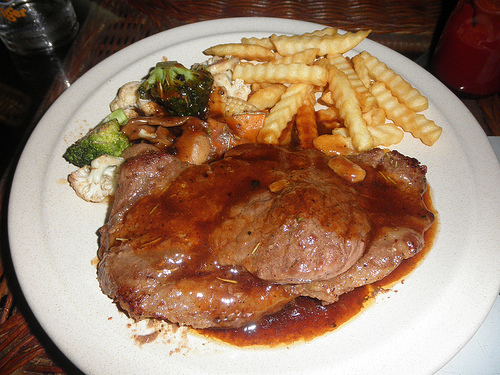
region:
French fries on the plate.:
[219, 44, 414, 136]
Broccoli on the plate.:
[71, 121, 138, 164]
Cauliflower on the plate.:
[53, 158, 115, 208]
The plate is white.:
[18, 220, 105, 335]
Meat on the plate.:
[136, 195, 391, 313]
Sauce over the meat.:
[163, 169, 358, 234]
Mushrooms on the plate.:
[118, 108, 200, 148]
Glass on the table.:
[3, 0, 79, 55]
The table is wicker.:
[91, 2, 266, 36]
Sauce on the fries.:
[276, 95, 338, 137]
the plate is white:
[43, 247, 120, 343]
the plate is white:
[68, 289, 158, 369]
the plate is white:
[16, 246, 142, 371]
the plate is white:
[33, 197, 176, 349]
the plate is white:
[52, 280, 92, 322]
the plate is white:
[61, 261, 213, 371]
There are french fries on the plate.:
[257, 19, 390, 136]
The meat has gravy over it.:
[297, 162, 429, 293]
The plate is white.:
[318, 240, 450, 373]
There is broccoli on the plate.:
[131, 58, 218, 110]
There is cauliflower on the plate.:
[52, 152, 129, 207]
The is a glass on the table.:
[2, 28, 79, 80]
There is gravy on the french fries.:
[311, 137, 403, 201]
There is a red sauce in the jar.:
[430, 30, 497, 92]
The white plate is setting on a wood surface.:
[4, 287, 75, 367]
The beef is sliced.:
[240, 217, 417, 339]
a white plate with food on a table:
[12, 1, 480, 366]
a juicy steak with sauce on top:
[110, 162, 418, 315]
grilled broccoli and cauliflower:
[65, 61, 150, 188]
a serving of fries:
[226, 26, 444, 151]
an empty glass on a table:
[0, 0, 85, 58]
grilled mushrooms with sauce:
[130, 111, 205, 152]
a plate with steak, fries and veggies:
[85, 45, 450, 345]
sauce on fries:
[260, 95, 345, 160]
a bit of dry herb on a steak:
[212, 270, 238, 287]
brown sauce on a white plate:
[287, 302, 342, 339]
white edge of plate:
[458, 300, 498, 350]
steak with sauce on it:
[98, 150, 389, 307]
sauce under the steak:
[235, 300, 372, 372]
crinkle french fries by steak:
[230, 54, 347, 104]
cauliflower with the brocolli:
[68, 115, 160, 202]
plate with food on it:
[55, 85, 498, 349]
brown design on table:
[31, 42, 101, 78]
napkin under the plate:
[452, 320, 496, 364]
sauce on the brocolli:
[135, 68, 223, 115]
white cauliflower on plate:
[71, 156, 146, 208]